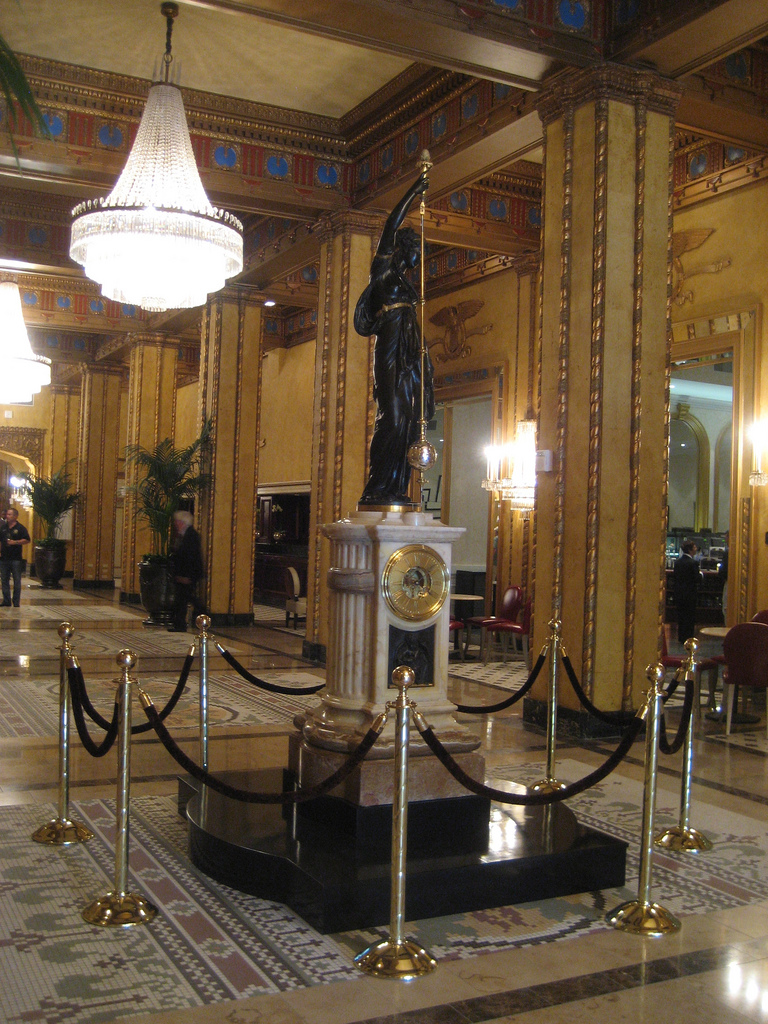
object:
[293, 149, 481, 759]
statue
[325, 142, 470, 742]
statue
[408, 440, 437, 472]
globe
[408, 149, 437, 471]
rod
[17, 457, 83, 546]
tree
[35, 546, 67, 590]
pot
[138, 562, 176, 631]
pot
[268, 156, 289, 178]
blue design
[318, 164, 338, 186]
blue design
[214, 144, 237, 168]
blue design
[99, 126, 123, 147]
blue design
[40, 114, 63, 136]
blue design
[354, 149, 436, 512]
statue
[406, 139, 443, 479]
rod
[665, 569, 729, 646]
counter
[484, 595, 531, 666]
red chair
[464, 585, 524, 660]
red chair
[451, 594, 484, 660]
table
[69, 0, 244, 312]
chandelier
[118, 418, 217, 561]
plant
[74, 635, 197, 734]
rope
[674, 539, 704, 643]
man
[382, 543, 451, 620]
clock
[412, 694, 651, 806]
rope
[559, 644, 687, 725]
rope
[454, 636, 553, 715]
rope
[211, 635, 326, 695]
rope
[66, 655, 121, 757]
rope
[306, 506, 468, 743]
column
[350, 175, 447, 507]
statue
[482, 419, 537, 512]
light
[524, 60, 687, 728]
pillar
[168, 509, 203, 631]
man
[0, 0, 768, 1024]
building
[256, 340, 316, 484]
wall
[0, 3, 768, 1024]
room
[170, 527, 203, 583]
suit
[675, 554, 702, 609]
suit